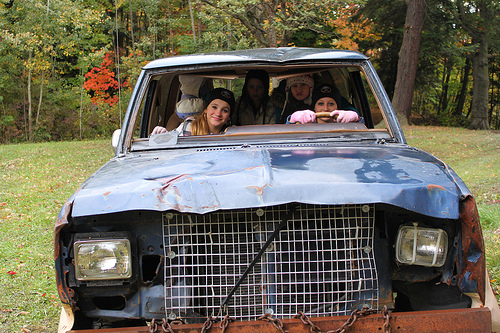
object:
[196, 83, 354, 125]
people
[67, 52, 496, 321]
car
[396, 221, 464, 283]
headlight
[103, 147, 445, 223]
hood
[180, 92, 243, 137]
woman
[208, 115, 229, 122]
mouth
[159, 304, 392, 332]
chain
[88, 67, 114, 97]
leaves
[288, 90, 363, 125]
girl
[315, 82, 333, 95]
cap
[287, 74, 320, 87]
cap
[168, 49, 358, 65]
roof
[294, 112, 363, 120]
hands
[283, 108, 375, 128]
steering wheel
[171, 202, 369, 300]
grill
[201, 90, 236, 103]
hat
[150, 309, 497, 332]
bumper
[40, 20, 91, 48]
leaves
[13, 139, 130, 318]
field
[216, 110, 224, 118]
nose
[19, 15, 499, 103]
trees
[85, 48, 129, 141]
tree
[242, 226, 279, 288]
thread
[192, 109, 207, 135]
hair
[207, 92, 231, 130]
head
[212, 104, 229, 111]
eye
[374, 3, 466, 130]
tree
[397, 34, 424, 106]
trunk